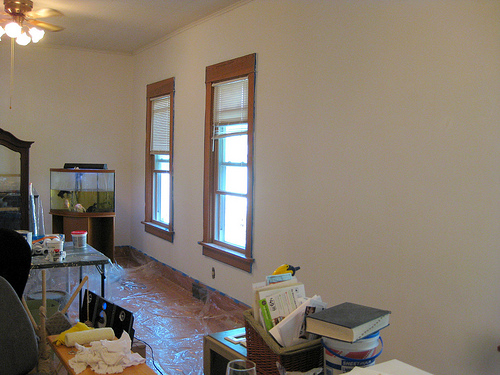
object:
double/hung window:
[212, 77, 248, 254]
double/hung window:
[150, 93, 171, 230]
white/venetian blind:
[210, 76, 249, 139]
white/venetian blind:
[149, 93, 171, 154]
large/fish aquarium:
[49, 167, 115, 213]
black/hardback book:
[305, 302, 392, 344]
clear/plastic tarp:
[145, 293, 200, 328]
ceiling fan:
[0, 0, 66, 32]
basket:
[243, 309, 325, 374]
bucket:
[321, 330, 384, 372]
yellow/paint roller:
[64, 326, 115, 347]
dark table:
[30, 241, 110, 298]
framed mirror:
[0, 127, 35, 231]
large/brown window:
[141, 76, 175, 243]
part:
[326, 91, 444, 228]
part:
[226, 356, 260, 373]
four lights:
[0, 23, 46, 47]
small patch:
[175, 317, 200, 372]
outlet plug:
[212, 267, 215, 280]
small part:
[72, 247, 82, 258]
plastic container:
[71, 230, 88, 249]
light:
[0, 26, 7, 39]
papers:
[269, 294, 323, 347]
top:
[227, 359, 256, 372]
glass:
[226, 359, 257, 375]